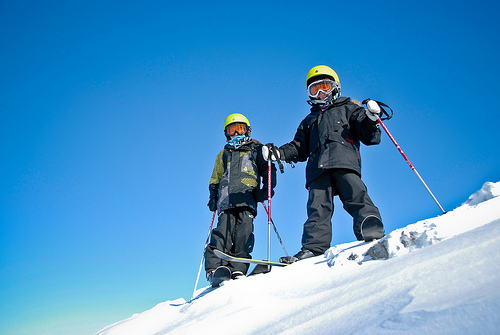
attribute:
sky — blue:
[19, 16, 191, 214]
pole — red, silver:
[370, 110, 449, 216]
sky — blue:
[6, 11, 192, 240]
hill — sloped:
[89, 191, 485, 332]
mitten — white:
[363, 97, 381, 124]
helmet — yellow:
[303, 63, 342, 95]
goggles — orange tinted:
[224, 121, 252, 138]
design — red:
[375, 116, 415, 171]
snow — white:
[94, 180, 484, 332]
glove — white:
[260, 143, 280, 163]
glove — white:
[363, 97, 382, 123]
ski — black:
[210, 247, 300, 266]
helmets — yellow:
[265, 49, 374, 100]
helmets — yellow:
[295, 63, 378, 86]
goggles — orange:
[303, 71, 346, 101]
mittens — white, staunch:
[352, 99, 423, 149]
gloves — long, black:
[188, 161, 256, 217]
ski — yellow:
[207, 237, 367, 295]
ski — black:
[317, 216, 406, 256]